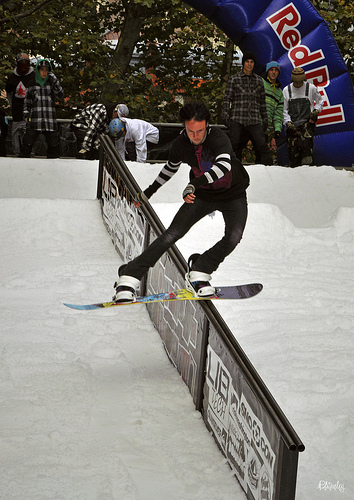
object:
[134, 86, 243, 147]
black hair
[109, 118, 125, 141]
helmet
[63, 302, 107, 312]
sign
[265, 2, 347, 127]
red bull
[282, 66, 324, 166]
man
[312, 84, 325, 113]
sleeve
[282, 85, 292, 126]
sleeve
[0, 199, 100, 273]
snow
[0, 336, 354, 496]
ground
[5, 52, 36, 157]
men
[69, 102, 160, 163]
men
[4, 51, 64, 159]
men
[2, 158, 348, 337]
ground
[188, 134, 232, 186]
sleeve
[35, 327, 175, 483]
snow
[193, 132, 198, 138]
nose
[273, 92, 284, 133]
sleeves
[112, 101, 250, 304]
guy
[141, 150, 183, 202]
sleeve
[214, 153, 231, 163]
stripe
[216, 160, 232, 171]
stripe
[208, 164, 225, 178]
stripe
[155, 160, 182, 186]
stripe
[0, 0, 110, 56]
trees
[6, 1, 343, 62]
background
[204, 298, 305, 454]
rail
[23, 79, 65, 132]
jacket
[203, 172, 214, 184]
stripe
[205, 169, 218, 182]
stripe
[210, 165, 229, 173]
stripe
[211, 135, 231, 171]
cloth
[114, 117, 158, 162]
clothes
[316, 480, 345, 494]
name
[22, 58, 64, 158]
guy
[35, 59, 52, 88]
hood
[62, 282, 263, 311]
snow board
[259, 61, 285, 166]
guy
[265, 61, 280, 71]
blue bonnet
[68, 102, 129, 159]
person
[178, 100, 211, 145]
head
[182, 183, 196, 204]
hand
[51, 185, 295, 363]
photo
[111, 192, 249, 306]
turn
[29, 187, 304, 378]
event